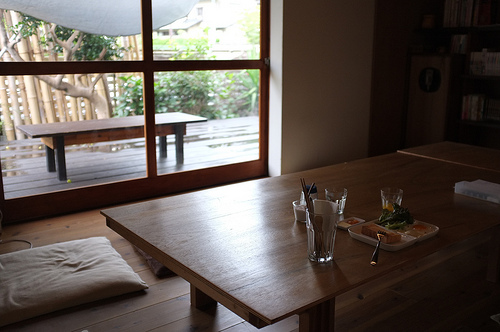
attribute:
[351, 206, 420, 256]
tray — white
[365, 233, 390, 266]
fork — silver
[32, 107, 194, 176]
bench — wooden, brown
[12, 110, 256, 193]
porch — wet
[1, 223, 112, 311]
pillow — tan, off-white, cream-colored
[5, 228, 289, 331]
floor — brown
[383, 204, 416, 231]
vegetables — green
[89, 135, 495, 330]
table — wooden, light brown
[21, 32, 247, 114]
tree — in background, growing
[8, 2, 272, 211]
window — in background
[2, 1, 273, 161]
frame — wooden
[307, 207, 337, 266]
cup — glass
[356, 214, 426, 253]
plate — white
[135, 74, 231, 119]
leaves — green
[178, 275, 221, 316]
legs — short